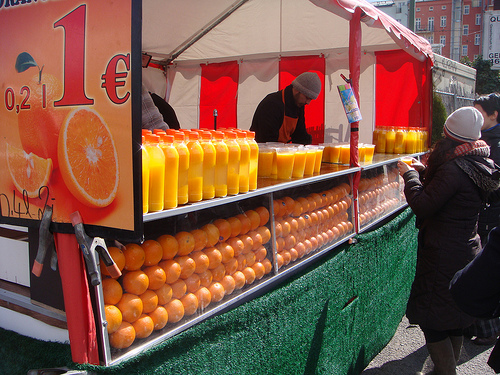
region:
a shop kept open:
[65, 1, 488, 373]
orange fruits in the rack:
[83, 168, 462, 311]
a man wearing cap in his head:
[443, 99, 485, 146]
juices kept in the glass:
[262, 134, 325, 172]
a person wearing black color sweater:
[423, 152, 490, 276]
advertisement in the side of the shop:
[2, 3, 123, 230]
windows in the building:
[426, 10, 484, 50]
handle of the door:
[210, 108, 220, 131]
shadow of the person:
[320, 303, 428, 373]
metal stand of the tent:
[342, 8, 369, 165]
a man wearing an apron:
[251, 69, 321, 142]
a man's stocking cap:
[290, 71, 321, 96]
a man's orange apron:
[278, 89, 298, 142]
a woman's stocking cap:
[442, 103, 483, 142]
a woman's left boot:
[431, 337, 456, 374]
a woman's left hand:
[394, 158, 418, 178]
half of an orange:
[58, 105, 121, 205]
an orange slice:
[4, 142, 55, 199]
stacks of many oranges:
[102, 165, 407, 345]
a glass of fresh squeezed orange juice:
[275, 146, 295, 178]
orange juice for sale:
[57, 36, 493, 304]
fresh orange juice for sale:
[154, 48, 471, 251]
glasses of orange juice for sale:
[217, 98, 317, 173]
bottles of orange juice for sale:
[127, 107, 336, 219]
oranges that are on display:
[68, 203, 429, 281]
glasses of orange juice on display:
[264, 107, 353, 190]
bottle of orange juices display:
[116, 83, 336, 187]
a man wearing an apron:
[232, 44, 357, 167]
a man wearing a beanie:
[232, 32, 336, 173]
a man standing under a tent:
[51, 4, 476, 372]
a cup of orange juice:
[275, 146, 295, 181]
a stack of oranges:
[104, 219, 255, 344]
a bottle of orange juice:
[146, 133, 165, 210]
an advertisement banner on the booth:
[1, 0, 139, 237]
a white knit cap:
[443, 106, 483, 141]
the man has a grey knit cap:
[291, 71, 321, 99]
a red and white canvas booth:
[321, 0, 433, 151]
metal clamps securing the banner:
[68, 210, 122, 287]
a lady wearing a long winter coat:
[403, 146, 498, 321]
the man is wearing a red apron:
[278, 88, 298, 145]